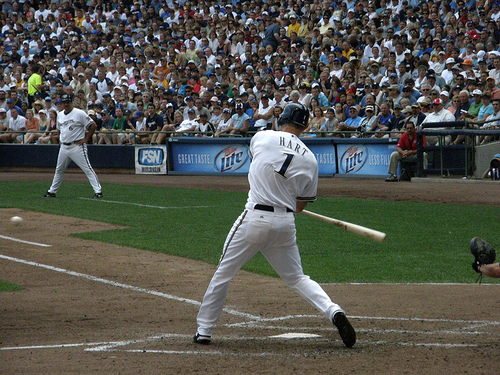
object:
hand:
[296, 198, 307, 213]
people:
[0, 2, 500, 142]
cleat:
[334, 309, 357, 351]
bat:
[298, 209, 387, 242]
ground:
[376, 161, 413, 212]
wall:
[0, 140, 414, 176]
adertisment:
[163, 139, 402, 177]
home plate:
[271, 333, 320, 338]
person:
[192, 101, 357, 348]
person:
[44, 95, 105, 201]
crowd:
[0, 1, 500, 145]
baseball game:
[0, 139, 498, 375]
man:
[385, 121, 432, 183]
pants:
[195, 204, 345, 336]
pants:
[47, 142, 104, 193]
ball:
[10, 216, 23, 226]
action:
[144, 77, 424, 357]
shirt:
[397, 132, 427, 153]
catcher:
[469, 236, 498, 264]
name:
[278, 135, 311, 156]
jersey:
[247, 129, 319, 212]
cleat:
[193, 332, 214, 344]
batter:
[194, 102, 357, 349]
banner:
[134, 144, 167, 175]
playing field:
[0, 166, 500, 375]